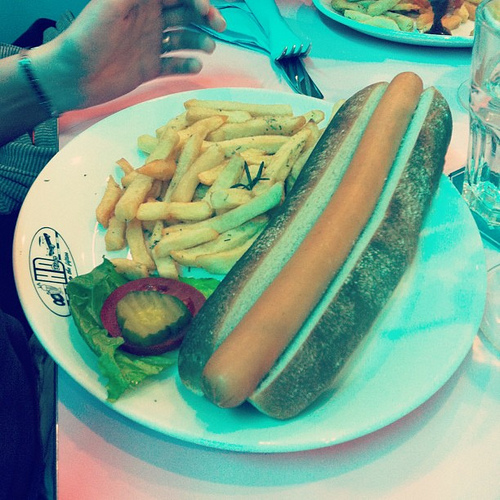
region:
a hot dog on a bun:
[188, 77, 440, 495]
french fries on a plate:
[60, 98, 331, 246]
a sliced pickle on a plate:
[101, 298, 201, 348]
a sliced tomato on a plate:
[77, 276, 199, 356]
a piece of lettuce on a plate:
[55, 260, 197, 362]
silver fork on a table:
[260, 35, 331, 71]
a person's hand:
[26, 3, 236, 148]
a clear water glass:
[456, 21, 496, 254]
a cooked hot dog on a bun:
[45, 73, 427, 493]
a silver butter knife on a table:
[250, 48, 352, 100]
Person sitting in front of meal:
[3, 35, 487, 487]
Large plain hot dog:
[171, 67, 456, 419]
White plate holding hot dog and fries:
[7, 81, 487, 461]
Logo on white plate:
[25, 222, 83, 319]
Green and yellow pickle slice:
[113, 286, 191, 348]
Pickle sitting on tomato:
[94, 277, 206, 355]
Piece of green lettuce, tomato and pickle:
[58, 260, 223, 403]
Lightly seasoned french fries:
[91, 100, 330, 282]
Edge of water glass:
[463, 0, 498, 245]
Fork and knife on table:
[203, 0, 330, 97]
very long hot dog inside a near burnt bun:
[201, 70, 423, 407]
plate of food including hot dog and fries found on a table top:
[13, 86, 486, 453]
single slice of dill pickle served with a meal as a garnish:
[115, 286, 187, 343]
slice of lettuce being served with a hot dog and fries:
[64, 258, 229, 405]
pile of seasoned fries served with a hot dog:
[95, 98, 327, 278]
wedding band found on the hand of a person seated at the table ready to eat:
[161, 33, 173, 50]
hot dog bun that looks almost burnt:
[178, 81, 455, 419]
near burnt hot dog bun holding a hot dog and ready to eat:
[177, 80, 452, 419]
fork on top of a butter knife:
[246, 0, 313, 62]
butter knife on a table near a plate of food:
[243, 0, 324, 100]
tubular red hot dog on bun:
[198, 68, 425, 413]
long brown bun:
[168, 69, 460, 424]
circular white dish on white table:
[10, 84, 492, 454]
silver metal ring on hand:
[161, 27, 173, 56]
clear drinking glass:
[456, 0, 498, 240]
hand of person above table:
[1, 0, 232, 154]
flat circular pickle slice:
[113, 288, 194, 348]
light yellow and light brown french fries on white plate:
[88, 96, 350, 283]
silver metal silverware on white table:
[233, 0, 328, 103]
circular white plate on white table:
[310, 0, 498, 56]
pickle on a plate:
[111, 288, 191, 343]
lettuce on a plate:
[66, 280, 113, 375]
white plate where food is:
[405, 262, 486, 424]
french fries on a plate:
[138, 101, 278, 238]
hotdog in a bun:
[181, 63, 450, 420]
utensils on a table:
[248, 7, 325, 100]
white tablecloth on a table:
[368, 440, 490, 489]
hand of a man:
[29, 3, 239, 113]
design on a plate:
[26, 219, 80, 324]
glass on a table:
[461, 0, 498, 239]